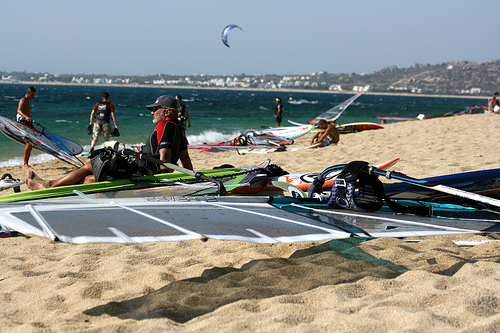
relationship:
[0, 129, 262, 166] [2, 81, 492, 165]
waves on water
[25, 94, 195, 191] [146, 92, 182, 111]
man wearing cap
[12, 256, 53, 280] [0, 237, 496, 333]
footprints in sand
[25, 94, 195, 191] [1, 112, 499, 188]
man laying on sand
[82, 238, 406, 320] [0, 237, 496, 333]
shadow in sand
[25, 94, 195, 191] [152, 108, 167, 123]
man has beard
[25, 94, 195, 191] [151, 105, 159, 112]
man wearing sunglasses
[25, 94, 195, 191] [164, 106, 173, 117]
man has ear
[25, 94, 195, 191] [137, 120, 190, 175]
man wearing wetsuit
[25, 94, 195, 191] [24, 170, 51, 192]
man has feet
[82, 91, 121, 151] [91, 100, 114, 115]
man wearing shirt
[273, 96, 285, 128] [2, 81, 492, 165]
person looking at water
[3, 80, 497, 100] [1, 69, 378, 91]
sand in front of houses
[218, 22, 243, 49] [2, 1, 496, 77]
kite in sky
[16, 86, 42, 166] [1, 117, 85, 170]
man holding board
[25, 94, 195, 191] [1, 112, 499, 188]
man lounging on sand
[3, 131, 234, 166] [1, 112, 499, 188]
waves next to sand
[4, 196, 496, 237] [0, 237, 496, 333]
surfboard on sand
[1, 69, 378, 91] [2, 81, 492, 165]
houses next to water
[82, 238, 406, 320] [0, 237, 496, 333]
shadow on sand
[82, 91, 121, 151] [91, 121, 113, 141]
man wearing shorts